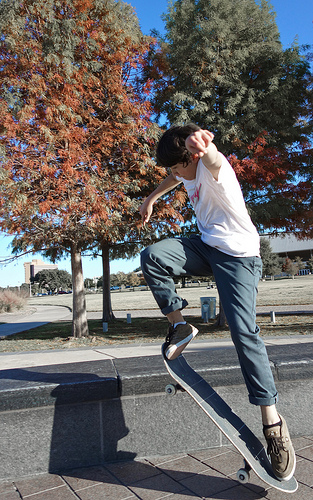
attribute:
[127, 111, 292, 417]
boy — close, small, white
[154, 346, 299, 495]
board — raised, long, black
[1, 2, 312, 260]
trees — orange, green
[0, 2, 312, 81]
sky — open, big, clear, blue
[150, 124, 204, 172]
hair — short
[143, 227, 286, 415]
trouser — folded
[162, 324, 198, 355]
shoe — brown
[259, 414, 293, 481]
shoe — brown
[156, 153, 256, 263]
shirt — white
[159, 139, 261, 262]
shirt — white